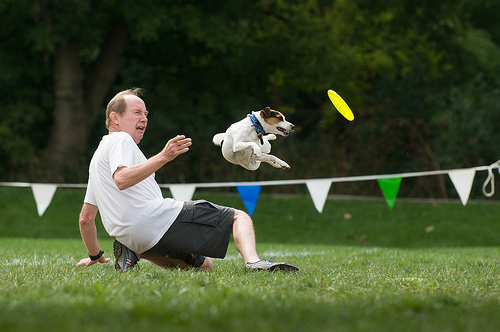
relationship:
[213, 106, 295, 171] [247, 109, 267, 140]
dog has a collar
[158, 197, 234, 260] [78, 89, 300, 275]
brown shorts on man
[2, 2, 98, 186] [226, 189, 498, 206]
large tree by trail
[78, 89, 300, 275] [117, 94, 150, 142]
man with an odd face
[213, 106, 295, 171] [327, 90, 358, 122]
dog after a frisbee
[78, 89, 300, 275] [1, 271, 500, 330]
man on ground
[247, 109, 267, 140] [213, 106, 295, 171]
collar on dog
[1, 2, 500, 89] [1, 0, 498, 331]
trees along park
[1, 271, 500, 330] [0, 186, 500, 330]
grass in field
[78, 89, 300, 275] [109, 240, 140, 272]
man has sneakers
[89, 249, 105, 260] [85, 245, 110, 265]
watch on mans wrist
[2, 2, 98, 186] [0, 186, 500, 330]
tree bordering field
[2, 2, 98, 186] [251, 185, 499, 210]
tree along pathway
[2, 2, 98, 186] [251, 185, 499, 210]
tree on pathway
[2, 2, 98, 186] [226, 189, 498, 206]
tree on trail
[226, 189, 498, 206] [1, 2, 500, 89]
paved trail has trees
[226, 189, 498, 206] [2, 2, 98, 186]
pathway has a tree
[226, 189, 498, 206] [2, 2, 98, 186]
walkway borders a tree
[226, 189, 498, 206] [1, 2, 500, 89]
paved trail runs along trees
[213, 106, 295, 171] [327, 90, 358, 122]
dog catches frisbee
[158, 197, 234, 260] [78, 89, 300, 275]
shorts on man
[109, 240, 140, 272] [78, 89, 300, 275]
sneakers on man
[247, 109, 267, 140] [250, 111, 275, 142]
collar around dogs neck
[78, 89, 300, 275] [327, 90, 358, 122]
man playing frisbee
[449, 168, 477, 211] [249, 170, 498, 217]
flags on a banner